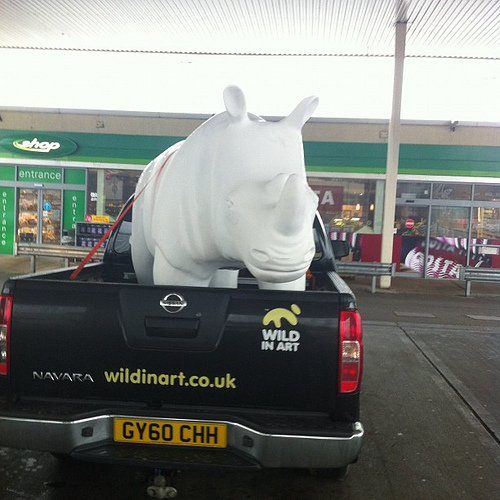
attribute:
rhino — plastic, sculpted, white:
[128, 84, 322, 289]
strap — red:
[68, 150, 175, 283]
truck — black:
[0, 190, 366, 495]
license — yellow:
[113, 417, 229, 448]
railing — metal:
[11, 239, 107, 275]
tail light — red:
[340, 311, 364, 396]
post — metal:
[379, 21, 411, 289]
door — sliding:
[12, 181, 65, 251]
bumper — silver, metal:
[0, 402, 365, 471]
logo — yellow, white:
[260, 300, 302, 353]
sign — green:
[0, 131, 81, 156]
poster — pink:
[307, 185, 345, 212]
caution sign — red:
[403, 213, 419, 231]